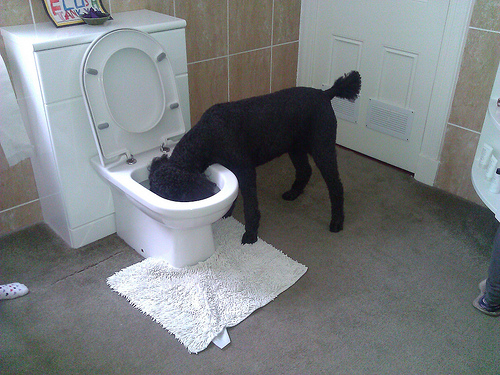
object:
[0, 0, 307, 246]
wall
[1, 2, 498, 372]
bathroom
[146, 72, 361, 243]
black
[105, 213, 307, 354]
floor mat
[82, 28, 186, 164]
seat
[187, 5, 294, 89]
tiles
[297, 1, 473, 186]
door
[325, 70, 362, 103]
tail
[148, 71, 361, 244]
black dog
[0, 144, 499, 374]
floor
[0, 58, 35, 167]
paper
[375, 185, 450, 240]
flooring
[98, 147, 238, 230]
bowl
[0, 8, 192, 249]
tank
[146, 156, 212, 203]
head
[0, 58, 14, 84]
roll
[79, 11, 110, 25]
bowl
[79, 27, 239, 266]
toilet